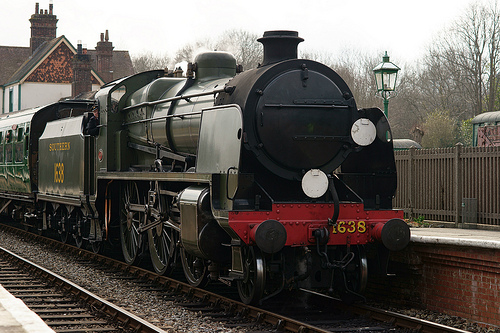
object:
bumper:
[228, 204, 411, 255]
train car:
[0, 89, 102, 204]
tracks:
[0, 224, 499, 333]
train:
[0, 30, 412, 306]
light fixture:
[372, 50, 401, 100]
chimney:
[94, 29, 115, 83]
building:
[0, 3, 135, 114]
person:
[86, 105, 99, 136]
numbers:
[53, 163, 65, 183]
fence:
[391, 145, 500, 226]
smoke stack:
[256, 30, 304, 68]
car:
[0, 101, 56, 203]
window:
[17, 127, 24, 141]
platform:
[410, 226, 498, 332]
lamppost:
[372, 50, 400, 141]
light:
[301, 169, 329, 198]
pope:
[121, 84, 234, 114]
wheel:
[117, 180, 145, 264]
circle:
[351, 118, 377, 146]